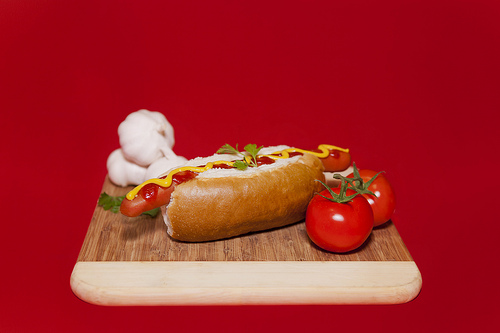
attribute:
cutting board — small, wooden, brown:
[70, 165, 423, 305]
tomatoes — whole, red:
[306, 164, 396, 253]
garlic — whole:
[107, 108, 189, 186]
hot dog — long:
[120, 144, 351, 242]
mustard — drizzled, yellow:
[124, 143, 350, 200]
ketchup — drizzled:
[141, 148, 340, 207]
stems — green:
[317, 161, 383, 204]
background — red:
[1, 0, 500, 332]